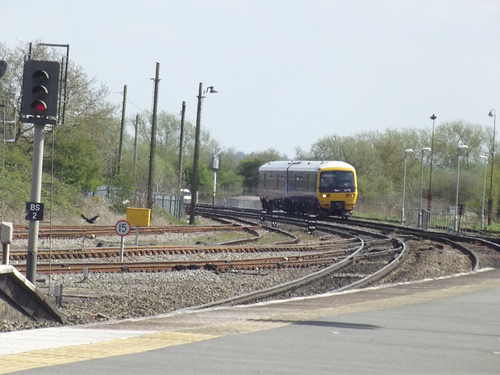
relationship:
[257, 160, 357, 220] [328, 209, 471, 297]
train on track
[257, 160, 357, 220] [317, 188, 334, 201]
train has head light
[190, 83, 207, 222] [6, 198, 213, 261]
pole beside track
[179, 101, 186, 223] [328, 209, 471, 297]
pole beside track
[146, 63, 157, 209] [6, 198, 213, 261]
pole beside track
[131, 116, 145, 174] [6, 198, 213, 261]
pole beside track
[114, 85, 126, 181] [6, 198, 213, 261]
pole beside track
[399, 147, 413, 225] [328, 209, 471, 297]
pole beside track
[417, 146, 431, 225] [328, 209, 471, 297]
pole beside track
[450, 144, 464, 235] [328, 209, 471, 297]
pole beside track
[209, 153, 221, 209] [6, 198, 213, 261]
pole beside track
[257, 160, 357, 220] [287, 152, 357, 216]
train has car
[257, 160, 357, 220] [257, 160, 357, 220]
train has train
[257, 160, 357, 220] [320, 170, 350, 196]
train has windshield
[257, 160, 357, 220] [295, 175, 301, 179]
train has window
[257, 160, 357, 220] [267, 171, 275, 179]
train has window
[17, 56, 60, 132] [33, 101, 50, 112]
traffic signal has red circle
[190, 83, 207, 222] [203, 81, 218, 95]
pole has light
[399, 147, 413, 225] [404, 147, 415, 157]
pole has light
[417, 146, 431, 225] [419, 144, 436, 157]
pole has light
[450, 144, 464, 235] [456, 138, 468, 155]
pole has light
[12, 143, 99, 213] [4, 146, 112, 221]
bushes are on hill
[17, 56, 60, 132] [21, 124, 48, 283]
traffic signal on top of pole